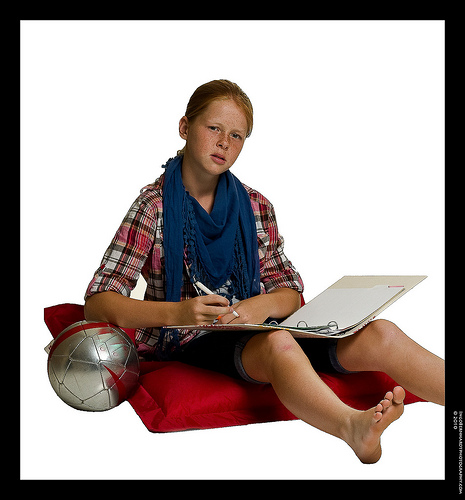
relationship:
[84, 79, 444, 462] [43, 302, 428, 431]
girl on top of pillow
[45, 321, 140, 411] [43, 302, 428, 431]
ball next to pillow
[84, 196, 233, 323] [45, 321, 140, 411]
arm on top of ball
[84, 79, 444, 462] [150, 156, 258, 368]
girl has scarf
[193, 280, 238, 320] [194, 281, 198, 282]
pen has top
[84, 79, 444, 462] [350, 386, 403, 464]
girl has foot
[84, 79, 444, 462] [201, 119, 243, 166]
girl has face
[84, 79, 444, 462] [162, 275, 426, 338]
girl has note book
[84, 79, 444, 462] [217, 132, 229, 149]
girl has nose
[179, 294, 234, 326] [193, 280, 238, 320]
hand holding pen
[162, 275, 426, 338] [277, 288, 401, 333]
notebook has paper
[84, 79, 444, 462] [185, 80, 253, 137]
girl has red hair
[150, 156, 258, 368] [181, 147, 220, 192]
scarf around neck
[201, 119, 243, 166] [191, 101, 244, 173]
face has freckles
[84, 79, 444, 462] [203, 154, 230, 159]
girl has lip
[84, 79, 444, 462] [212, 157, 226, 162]
girl has lip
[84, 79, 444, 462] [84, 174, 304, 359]
girl has shirt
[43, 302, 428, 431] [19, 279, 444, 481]
pillow on top of floor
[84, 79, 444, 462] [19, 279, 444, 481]
girl on top of floor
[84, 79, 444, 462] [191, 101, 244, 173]
girl has freckles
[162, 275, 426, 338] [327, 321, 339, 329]
note book has ring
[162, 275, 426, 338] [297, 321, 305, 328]
note book has ring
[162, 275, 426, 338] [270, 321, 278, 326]
note book has ring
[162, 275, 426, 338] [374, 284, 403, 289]
note book has tabbed divider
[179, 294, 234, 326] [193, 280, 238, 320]
hand holds pen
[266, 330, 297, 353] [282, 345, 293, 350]
knee has scar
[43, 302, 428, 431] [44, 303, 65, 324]
pillow has corner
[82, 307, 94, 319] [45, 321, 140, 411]
elbow on top of ball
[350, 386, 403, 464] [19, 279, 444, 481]
foot on top of floor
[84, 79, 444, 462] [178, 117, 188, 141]
girl has right ear